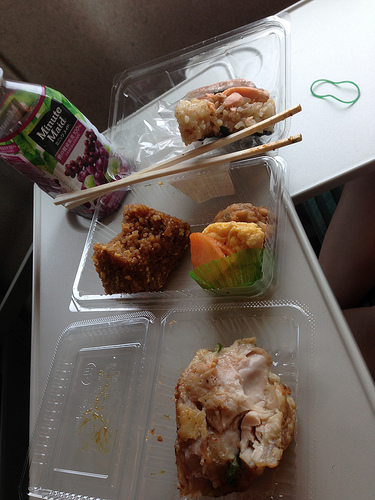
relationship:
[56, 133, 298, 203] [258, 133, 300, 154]
chopstick has foot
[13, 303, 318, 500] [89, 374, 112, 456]
plastic has sauce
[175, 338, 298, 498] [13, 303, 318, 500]
meat in plastic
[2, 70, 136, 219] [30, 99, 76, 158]
bottle has logo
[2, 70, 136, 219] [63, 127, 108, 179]
bottle has grapes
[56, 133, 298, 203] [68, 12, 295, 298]
chopstick on top of box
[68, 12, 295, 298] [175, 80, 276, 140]
box has food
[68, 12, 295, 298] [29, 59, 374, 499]
box on top of tray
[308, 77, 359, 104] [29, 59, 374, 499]
band on top of tray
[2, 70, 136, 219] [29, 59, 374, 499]
bottle on top of tray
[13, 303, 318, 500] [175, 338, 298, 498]
plastic has meat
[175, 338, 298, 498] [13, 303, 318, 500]
meat inside plastic